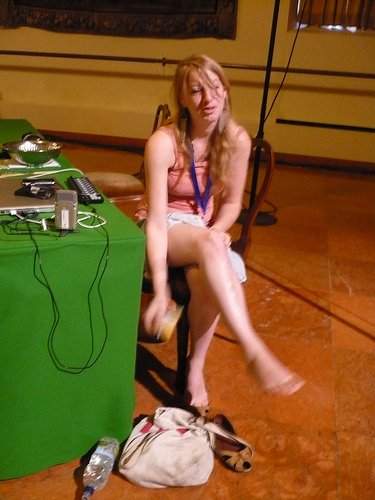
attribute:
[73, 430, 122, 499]
bottle — water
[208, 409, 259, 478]
shoe — sitting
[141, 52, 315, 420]
girl — sitting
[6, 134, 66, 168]
bowl — silver, metal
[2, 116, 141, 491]
cloth — green, fitted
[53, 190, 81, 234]
speaker — silver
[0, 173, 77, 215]
laptop — resting, silver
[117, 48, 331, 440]
woman — sitting, barefoot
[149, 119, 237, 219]
top — pink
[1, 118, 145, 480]
table — green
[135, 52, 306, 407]
woman — blonde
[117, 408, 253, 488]
bag — white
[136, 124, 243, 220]
tank top — peach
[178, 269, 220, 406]
leg —  left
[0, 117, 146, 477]
material — green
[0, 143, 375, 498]
floor — tile, in room, brown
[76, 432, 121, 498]
water bottle — transparent